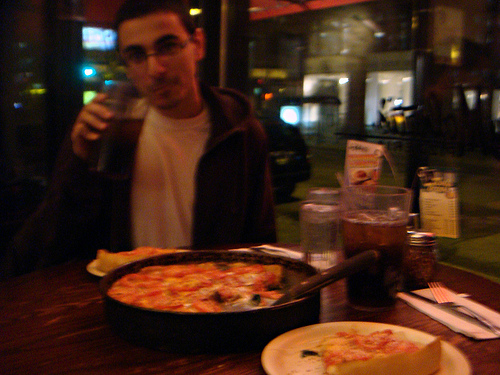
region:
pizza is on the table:
[99, 185, 337, 325]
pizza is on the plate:
[307, 315, 377, 365]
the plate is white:
[261, 329, 310, 369]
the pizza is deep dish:
[126, 232, 329, 364]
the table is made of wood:
[19, 263, 121, 374]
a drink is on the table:
[315, 170, 462, 330]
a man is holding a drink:
[62, 59, 279, 209]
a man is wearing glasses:
[107, 33, 272, 68]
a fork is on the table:
[417, 274, 489, 341]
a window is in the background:
[259, 45, 494, 163]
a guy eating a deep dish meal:
[34, 19, 465, 371]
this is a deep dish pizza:
[79, 226, 459, 372]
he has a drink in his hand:
[59, 59, 162, 184]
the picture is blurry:
[52, 18, 465, 273]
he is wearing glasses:
[89, 20, 219, 77]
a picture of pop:
[330, 149, 444, 318]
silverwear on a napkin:
[402, 265, 499, 340]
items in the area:
[288, 137, 472, 232]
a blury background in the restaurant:
[261, 54, 448, 138]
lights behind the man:
[52, 20, 115, 95]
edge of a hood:
[206, 109, 258, 154]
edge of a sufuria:
[168, 310, 211, 352]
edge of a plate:
[253, 321, 280, 358]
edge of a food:
[348, 331, 367, 348]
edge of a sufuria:
[268, 300, 283, 329]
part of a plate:
[277, 315, 304, 345]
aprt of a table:
[96, 336, 127, 360]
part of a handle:
[330, 254, 377, 297]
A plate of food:
[263, 316, 489, 371]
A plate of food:
[89, 236, 321, 340]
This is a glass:
[401, 220, 446, 301]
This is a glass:
[337, 173, 414, 310]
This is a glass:
[300, 171, 350, 282]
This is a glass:
[89, 63, 159, 201]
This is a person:
[31, 7, 276, 261]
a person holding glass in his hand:
[78, 58, 152, 193]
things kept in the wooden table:
[55, 228, 497, 370]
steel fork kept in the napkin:
[418, 273, 498, 323]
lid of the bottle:
[410, 228, 442, 251]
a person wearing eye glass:
[115, 28, 211, 62]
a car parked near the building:
[241, 123, 333, 193]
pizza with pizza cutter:
[123, 258, 307, 325]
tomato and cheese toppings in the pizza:
[133, 262, 248, 307]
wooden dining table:
[20, 280, 95, 369]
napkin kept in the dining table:
[409, 288, 493, 339]